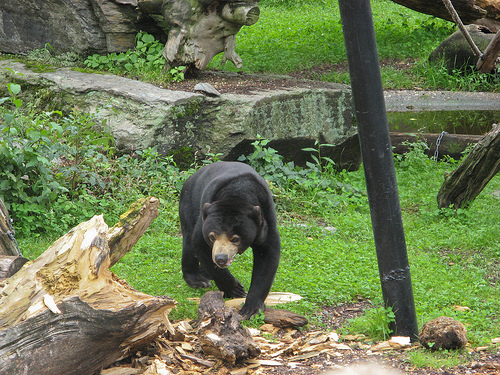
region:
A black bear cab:
[177, 156, 284, 316]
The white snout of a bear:
[200, 204, 255, 270]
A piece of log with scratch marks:
[6, 218, 165, 347]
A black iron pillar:
[336, 13, 433, 350]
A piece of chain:
[432, 129, 447, 160]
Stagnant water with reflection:
[396, 112, 490, 130]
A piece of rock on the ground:
[419, 315, 469, 352]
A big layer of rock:
[83, 80, 348, 159]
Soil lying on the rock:
[188, 74, 289, 89]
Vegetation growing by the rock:
[4, 90, 113, 206]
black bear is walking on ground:
[167, 151, 328, 313]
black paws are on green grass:
[160, 255, 290, 318]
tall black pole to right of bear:
[332, 8, 440, 341]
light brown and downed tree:
[3, 224, 200, 359]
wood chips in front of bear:
[167, 313, 377, 369]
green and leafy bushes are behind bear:
[14, 113, 315, 235]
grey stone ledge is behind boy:
[94, 68, 348, 169]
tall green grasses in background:
[247, 5, 407, 70]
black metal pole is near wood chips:
[345, 30, 439, 330]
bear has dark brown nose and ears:
[212, 233, 244, 268]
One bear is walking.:
[172, 158, 292, 322]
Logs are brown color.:
[23, 252, 184, 370]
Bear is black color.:
[158, 156, 284, 314]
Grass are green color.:
[308, 220, 357, 282]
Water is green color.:
[403, 103, 485, 140]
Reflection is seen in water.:
[387, 99, 496, 143]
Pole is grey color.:
[307, 30, 453, 301]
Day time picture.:
[22, 15, 497, 361]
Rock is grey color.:
[81, 76, 345, 166]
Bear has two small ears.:
[200, 198, 272, 233]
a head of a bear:
[196, 192, 270, 269]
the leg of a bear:
[248, 247, 283, 313]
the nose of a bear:
[207, 241, 237, 267]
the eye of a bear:
[228, 230, 244, 246]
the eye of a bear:
[206, 229, 217, 244]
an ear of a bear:
[250, 199, 269, 224]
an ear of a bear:
[199, 201, 212, 222]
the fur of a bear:
[211, 167, 237, 191]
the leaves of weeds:
[34, 125, 78, 182]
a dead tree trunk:
[38, 234, 174, 358]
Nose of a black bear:
[213, 251, 230, 266]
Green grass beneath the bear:
[308, 253, 349, 282]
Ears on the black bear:
[201, 200, 267, 217]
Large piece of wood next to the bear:
[1, 205, 163, 372]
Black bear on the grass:
[177, 163, 279, 311]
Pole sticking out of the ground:
[338, 40, 424, 342]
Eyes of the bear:
[208, 230, 238, 243]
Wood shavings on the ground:
[283, 331, 338, 356]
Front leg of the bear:
[249, 249, 271, 316]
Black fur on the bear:
[200, 179, 241, 201]